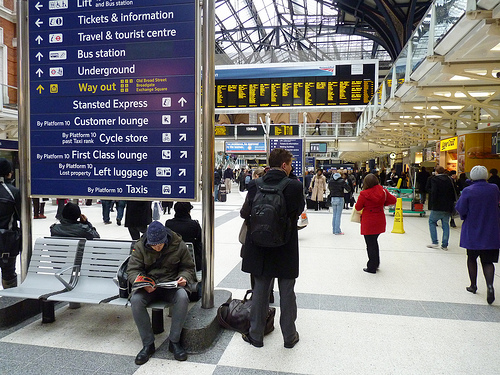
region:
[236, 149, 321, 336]
a person in station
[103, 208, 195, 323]
a person in station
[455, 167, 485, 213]
a person in station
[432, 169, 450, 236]
a person in station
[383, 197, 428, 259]
a yellow caution cone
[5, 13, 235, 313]
a sign in a station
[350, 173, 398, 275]
woman wearing a red coat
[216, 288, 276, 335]
black leather duffle bag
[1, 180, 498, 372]
white and grey tile flooring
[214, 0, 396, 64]
glass and metal skylight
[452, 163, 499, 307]
woman wearing a blue coat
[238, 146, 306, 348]
young man with short brown hair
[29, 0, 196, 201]
blue sign with white writing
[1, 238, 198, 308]
grey plastic seats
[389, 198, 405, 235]
yellow wet floor sign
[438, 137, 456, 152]
yellow sign with black writing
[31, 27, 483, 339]
this is a train station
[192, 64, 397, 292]
this is a train stop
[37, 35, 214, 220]
the signs are blue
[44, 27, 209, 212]
the signs are directive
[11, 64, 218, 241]
the text is white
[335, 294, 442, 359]
the ground is tiled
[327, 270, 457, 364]
the ground is white and gray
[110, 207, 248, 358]
the man is writing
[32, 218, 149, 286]
the bench is metal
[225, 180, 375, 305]
the person has a backpack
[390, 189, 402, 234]
caution for a wet floor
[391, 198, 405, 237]
a yellow pylon for caution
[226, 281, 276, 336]
a black duffle bag on the floor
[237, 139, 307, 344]
man with black coat and a black backpack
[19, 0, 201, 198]
a large sign offers direction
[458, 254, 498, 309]
a woman wears high brown boots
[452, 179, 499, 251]
a woman wears a purple car coat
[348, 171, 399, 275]
lady wears a red coat with black slacks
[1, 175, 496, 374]
a white floor with grey highlights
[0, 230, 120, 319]
light gey chairs with chrome arms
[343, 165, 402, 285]
a person is standing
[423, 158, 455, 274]
a person is standing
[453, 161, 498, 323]
a person is standing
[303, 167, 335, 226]
a person is standing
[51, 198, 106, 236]
a person is standing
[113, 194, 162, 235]
a person is standing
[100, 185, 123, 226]
a person is standing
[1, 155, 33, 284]
a person is standing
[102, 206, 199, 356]
man is reading a magazine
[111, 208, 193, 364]
man is reading a magazine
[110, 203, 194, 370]
man is reading a magazine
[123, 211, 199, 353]
man is reading a magazine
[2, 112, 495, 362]
people in a train station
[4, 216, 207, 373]
person sitting on a bench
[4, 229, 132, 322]
the bench is gray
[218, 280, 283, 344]
a bag on the floor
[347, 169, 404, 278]
woman wearing a red coat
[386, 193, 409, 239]
a yellow cone on the floor